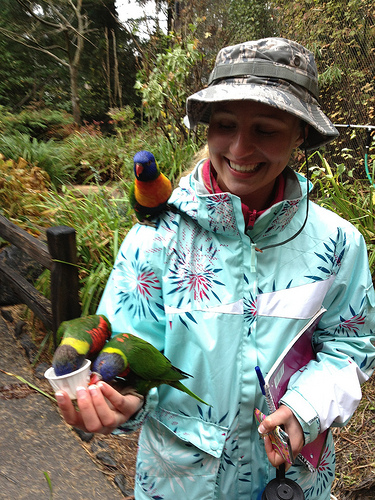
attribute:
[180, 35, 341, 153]
hat — green, camoflaged, camouflage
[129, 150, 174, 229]
parrot — yellow, green, orange, blue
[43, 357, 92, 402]
paper ramikin — little, white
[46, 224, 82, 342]
fence post — wooden, weathered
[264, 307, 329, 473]
note book — magenta, spiral bound, pink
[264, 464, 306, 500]
cover — black, plastic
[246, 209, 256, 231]
zipper — pink, metal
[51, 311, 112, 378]
parrot — green, yellow, eating, blue, orange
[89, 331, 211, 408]
parrot — green, yellow, eating, blue, orange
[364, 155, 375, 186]
hose — green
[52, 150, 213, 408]
three birds — colorful, eating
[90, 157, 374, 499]
jacket — light blue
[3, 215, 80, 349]
fence — wooden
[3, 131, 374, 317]
grass — green